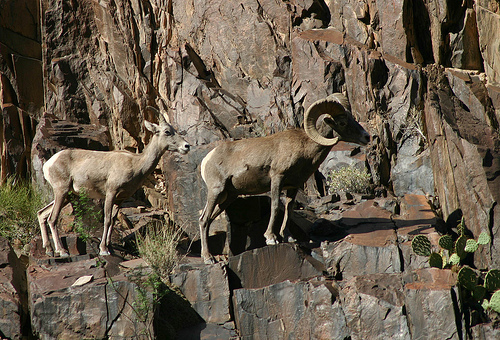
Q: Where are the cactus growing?
A: On the rocks.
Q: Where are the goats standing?
A: On the cliff.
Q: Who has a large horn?
A: Goat.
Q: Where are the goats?
A: On the mountainside.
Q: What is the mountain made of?
A: Rocks.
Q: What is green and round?
A: Catus.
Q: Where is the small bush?
A: On the rocks.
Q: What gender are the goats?
A: Male and female.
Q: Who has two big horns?
A: A sheep.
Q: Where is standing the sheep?
A: On cliff side.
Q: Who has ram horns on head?
A: A sheep.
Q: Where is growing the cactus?
A: On the rocky mountain.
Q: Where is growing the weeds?
A: On the mountain.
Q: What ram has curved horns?
A: The big one.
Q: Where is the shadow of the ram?
A: On the rock.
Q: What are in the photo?
A: Animals.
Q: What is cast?
A: Shadow.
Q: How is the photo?
A: Clear.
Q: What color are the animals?
A: Brown.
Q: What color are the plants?
A: Green.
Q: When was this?
A: Daytime.